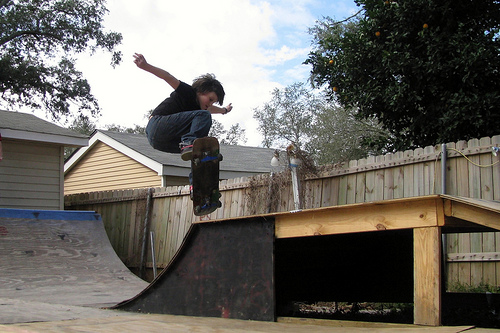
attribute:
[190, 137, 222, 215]
skateboard — wooden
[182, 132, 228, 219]
skateboard — black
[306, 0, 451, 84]
oranges — orange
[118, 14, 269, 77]
clouds — puffy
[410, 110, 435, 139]
ground — metal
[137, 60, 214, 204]
boy — jumping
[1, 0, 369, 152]
sky — blue, white, cloudy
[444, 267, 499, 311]
weeds — green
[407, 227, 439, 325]
leg — wooden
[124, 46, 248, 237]
boy — jumping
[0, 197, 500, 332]
ramp — gray , wooden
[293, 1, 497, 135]
tree — green, large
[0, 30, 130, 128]
tree — green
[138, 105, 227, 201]
pants — grey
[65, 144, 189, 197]
siding — beige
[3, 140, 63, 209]
siding — beige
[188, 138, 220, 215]
skateboard — black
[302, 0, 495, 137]
fruit tree — green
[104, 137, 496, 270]
fence — wooden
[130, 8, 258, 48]
cloud — white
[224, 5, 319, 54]
sky — blue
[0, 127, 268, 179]
trim — white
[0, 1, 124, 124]
tree — green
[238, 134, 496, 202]
fence — large, wooden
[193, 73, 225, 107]
hair — brown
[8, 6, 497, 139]
sky — blue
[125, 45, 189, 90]
arm — outstretched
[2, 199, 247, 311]
ramp — wood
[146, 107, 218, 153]
jeans — blue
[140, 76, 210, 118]
shirt — black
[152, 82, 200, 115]
shirt — black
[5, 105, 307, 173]
shingles — gray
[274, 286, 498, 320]
weeds — green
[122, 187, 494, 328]
platform — wooden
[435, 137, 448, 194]
pole — gray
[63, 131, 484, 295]
fence — brown, woden, wood, wooden